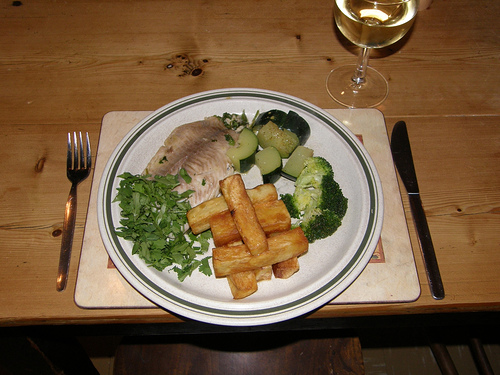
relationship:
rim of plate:
[100, 90, 377, 318] [74, 73, 413, 338]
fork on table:
[51, 125, 93, 292] [73, 105, 426, 315]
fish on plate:
[144, 115, 239, 219] [91, 78, 394, 333]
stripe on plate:
[102, 90, 378, 317] [91, 78, 394, 333]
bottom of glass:
[329, 62, 389, 108] [320, 47, 397, 107]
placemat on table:
[73, 107, 422, 308] [0, 2, 497, 323]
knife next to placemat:
[391, 121, 447, 306] [73, 107, 422, 308]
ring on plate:
[102, 89, 382, 320] [91, 78, 394, 333]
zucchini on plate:
[223, 101, 316, 176] [88, 91, 405, 316]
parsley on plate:
[113, 169, 213, 280] [91, 78, 394, 333]